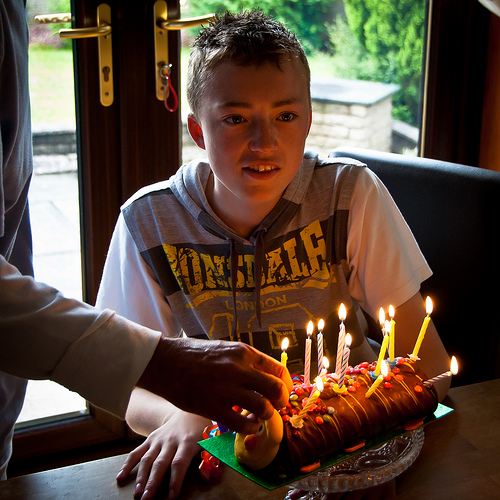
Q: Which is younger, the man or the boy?
A: The boy is younger than the man.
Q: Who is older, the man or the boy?
A: The man is older than the boy.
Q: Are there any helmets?
A: No, there are no helmets.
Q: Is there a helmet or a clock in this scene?
A: No, there are no helmets or clocks.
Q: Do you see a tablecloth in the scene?
A: No, there are no tablecloths.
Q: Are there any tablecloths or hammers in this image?
A: No, there are no tablecloths or hammers.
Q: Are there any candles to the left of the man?
A: No, the candle is to the right of the man.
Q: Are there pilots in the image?
A: No, there are no pilots.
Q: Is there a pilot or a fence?
A: No, there are no pilots or fences.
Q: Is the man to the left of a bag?
A: No, the man is to the left of a candle.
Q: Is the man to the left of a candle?
A: Yes, the man is to the left of a candle.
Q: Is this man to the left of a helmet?
A: No, the man is to the left of a candle.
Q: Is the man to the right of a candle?
A: No, the man is to the left of a candle.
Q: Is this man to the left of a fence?
A: No, the man is to the left of a candle.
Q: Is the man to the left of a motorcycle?
A: No, the man is to the left of the candle.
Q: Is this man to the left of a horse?
A: No, the man is to the left of a candle.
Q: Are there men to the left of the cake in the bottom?
A: Yes, there is a man to the left of the cake.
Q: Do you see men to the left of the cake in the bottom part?
A: Yes, there is a man to the left of the cake.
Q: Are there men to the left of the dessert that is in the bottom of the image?
A: Yes, there is a man to the left of the cake.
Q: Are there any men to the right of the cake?
A: No, the man is to the left of the cake.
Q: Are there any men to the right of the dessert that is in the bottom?
A: No, the man is to the left of the cake.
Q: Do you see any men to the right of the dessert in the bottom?
A: No, the man is to the left of the cake.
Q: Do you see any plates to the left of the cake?
A: No, there is a man to the left of the cake.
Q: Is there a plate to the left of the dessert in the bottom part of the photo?
A: No, there is a man to the left of the cake.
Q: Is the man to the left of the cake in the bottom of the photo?
A: Yes, the man is to the left of the cake.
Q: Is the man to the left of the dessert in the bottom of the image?
A: Yes, the man is to the left of the cake.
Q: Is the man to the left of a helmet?
A: No, the man is to the left of the cake.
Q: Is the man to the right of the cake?
A: No, the man is to the left of the cake.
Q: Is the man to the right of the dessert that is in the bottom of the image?
A: No, the man is to the left of the cake.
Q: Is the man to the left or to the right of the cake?
A: The man is to the left of the cake.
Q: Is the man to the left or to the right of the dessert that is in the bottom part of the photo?
A: The man is to the left of the cake.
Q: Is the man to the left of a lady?
A: No, the man is to the left of a candle.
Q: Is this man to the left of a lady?
A: No, the man is to the left of a candle.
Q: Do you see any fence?
A: No, there are no fences.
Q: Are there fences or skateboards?
A: No, there are no fences or skateboards.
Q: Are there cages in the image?
A: No, there are no cages.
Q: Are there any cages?
A: No, there are no cages.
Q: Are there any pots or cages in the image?
A: No, there are no cages or pots.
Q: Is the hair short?
A: Yes, the hair is short.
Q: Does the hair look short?
A: Yes, the hair is short.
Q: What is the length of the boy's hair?
A: The hair is short.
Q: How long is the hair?
A: The hair is short.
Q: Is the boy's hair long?
A: No, the hair is short.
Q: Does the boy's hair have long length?
A: No, the hair is short.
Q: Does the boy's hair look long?
A: No, the hair is short.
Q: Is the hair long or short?
A: The hair is short.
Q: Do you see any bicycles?
A: No, there are no bicycles.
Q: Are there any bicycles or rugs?
A: No, there are no bicycles or rugs.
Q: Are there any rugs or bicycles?
A: No, there are no bicycles or rugs.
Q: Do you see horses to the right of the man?
A: No, there is a candle to the right of the man.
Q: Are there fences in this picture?
A: No, there are no fences.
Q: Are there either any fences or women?
A: No, there are no fences or women.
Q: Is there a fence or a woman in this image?
A: No, there are no fences or women.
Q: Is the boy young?
A: Yes, the boy is young.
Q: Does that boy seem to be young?
A: Yes, the boy is young.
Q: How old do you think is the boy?
A: The boy is young.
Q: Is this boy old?
A: No, the boy is young.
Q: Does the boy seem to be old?
A: No, the boy is young.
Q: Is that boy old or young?
A: The boy is young.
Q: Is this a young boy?
A: Yes, this is a young boy.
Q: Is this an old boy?
A: No, this is a young boy.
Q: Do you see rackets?
A: No, there are no rackets.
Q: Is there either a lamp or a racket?
A: No, there are no rackets or lamps.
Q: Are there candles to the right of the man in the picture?
A: Yes, there is a candle to the right of the man.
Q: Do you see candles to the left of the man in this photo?
A: No, the candle is to the right of the man.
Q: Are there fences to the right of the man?
A: No, there is a candle to the right of the man.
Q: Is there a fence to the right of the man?
A: No, there is a candle to the right of the man.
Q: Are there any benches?
A: No, there are no benches.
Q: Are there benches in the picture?
A: No, there are no benches.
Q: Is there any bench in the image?
A: No, there are no benches.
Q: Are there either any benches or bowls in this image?
A: No, there are no benches or bowls.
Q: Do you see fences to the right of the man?
A: No, there is a candle to the right of the man.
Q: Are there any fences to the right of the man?
A: No, there is a candle to the right of the man.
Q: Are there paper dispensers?
A: No, there are no paper dispensers.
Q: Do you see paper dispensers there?
A: No, there are no paper dispensers.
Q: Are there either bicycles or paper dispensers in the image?
A: No, there are no paper dispensers or bicycles.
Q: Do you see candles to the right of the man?
A: Yes, there is a candle to the right of the man.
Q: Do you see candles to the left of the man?
A: No, the candle is to the right of the man.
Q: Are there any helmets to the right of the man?
A: No, there is a candle to the right of the man.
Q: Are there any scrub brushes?
A: No, there are no scrub brushes.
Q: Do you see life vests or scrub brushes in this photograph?
A: No, there are no scrub brushes or life vests.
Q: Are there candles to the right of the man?
A: Yes, there is a candle to the right of the man.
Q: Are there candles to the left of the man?
A: No, the candle is to the right of the man.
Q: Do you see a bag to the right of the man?
A: No, there is a candle to the right of the man.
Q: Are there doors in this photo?
A: Yes, there is a door.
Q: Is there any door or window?
A: Yes, there is a door.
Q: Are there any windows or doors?
A: Yes, there is a door.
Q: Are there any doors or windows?
A: Yes, there is a door.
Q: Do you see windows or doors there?
A: Yes, there is a door.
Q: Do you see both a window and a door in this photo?
A: Yes, there are both a door and a window.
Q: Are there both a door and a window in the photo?
A: Yes, there are both a door and a window.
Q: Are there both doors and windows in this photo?
A: Yes, there are both a door and a window.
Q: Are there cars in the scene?
A: No, there are no cars.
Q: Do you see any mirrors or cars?
A: No, there are no cars or mirrors.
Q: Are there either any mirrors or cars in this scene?
A: No, there are no cars or mirrors.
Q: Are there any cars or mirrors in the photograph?
A: No, there are no cars or mirrors.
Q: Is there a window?
A: Yes, there is a window.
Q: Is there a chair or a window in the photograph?
A: Yes, there is a window.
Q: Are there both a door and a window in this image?
A: Yes, there are both a window and a door.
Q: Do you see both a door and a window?
A: Yes, there are both a window and a door.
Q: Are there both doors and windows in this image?
A: Yes, there are both a window and a door.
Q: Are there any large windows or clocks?
A: Yes, there is a large window.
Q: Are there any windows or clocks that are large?
A: Yes, the window is large.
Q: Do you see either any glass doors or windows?
A: Yes, there is a glass window.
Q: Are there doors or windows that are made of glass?
A: Yes, the window is made of glass.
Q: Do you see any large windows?
A: Yes, there is a large window.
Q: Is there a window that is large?
A: Yes, there is a window that is large.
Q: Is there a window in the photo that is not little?
A: Yes, there is a large window.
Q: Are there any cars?
A: No, there are no cars.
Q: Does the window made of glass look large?
A: Yes, the window is large.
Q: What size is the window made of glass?
A: The window is large.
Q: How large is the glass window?
A: The window is large.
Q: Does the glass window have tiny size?
A: No, the window is large.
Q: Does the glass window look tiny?
A: No, the window is large.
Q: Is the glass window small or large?
A: The window is large.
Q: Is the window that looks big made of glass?
A: Yes, the window is made of glass.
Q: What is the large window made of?
A: The window is made of glass.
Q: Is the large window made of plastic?
A: No, the window is made of glass.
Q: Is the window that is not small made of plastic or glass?
A: The window is made of glass.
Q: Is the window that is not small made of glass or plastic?
A: The window is made of glass.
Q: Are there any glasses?
A: No, there are no glasses.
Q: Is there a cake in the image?
A: Yes, there is a cake.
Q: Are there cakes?
A: Yes, there is a cake.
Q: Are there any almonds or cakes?
A: Yes, there is a cake.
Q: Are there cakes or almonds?
A: Yes, there is a cake.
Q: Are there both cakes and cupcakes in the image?
A: No, there is a cake but no cupcakes.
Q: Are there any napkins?
A: No, there are no napkins.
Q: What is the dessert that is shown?
A: The dessert is a cake.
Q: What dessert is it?
A: The dessert is a cake.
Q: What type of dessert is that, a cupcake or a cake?
A: That is a cake.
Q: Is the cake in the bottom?
A: Yes, the cake is in the bottom of the image.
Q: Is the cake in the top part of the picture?
A: No, the cake is in the bottom of the image.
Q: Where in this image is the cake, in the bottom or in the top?
A: The cake is in the bottom of the image.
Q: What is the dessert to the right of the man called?
A: The dessert is a cake.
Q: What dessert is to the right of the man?
A: The dessert is a cake.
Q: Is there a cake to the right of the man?
A: Yes, there is a cake to the right of the man.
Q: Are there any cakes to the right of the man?
A: Yes, there is a cake to the right of the man.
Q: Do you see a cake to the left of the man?
A: No, the cake is to the right of the man.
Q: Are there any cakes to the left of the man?
A: No, the cake is to the right of the man.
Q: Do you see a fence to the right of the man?
A: No, there is a cake to the right of the man.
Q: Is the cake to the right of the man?
A: Yes, the cake is to the right of the man.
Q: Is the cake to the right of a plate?
A: No, the cake is to the right of the man.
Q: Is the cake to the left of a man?
A: No, the cake is to the right of a man.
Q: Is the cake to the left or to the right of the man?
A: The cake is to the right of the man.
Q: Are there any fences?
A: No, there are no fences.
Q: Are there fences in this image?
A: No, there are no fences.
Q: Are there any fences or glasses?
A: No, there are no fences or glasses.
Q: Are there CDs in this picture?
A: No, there are no cds.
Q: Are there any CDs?
A: No, there are no cds.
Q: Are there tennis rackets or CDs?
A: No, there are no CDs or tennis rackets.